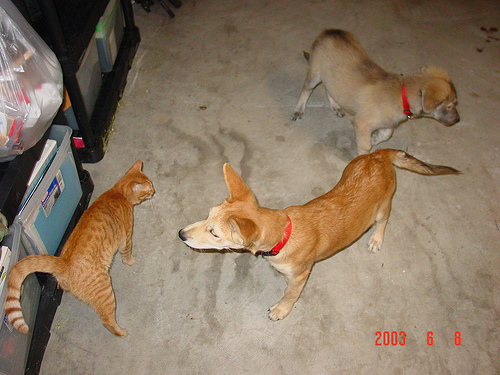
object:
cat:
[4, 159, 154, 339]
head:
[120, 159, 155, 204]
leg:
[88, 279, 117, 325]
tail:
[2, 255, 57, 334]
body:
[63, 194, 134, 289]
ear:
[126, 159, 143, 175]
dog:
[179, 147, 463, 321]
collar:
[400, 78, 413, 119]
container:
[76, 34, 103, 117]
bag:
[0, 1, 65, 163]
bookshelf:
[14, 0, 140, 164]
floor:
[39, 2, 499, 373]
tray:
[15, 124, 83, 256]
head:
[178, 196, 260, 251]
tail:
[387, 148, 461, 175]